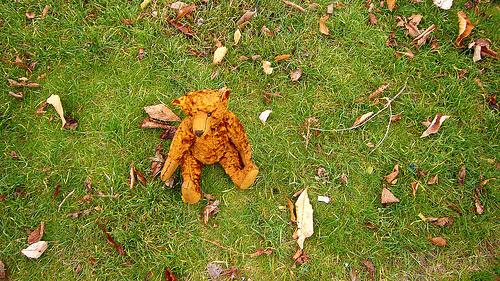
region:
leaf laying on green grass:
[45, 92, 77, 134]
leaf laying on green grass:
[26, 220, 42, 242]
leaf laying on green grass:
[18, 239, 47, 259]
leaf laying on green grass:
[293, 189, 314, 258]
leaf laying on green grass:
[128, 164, 133, 191]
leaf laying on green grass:
[133, 165, 147, 185]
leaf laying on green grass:
[164, 13, 196, 38]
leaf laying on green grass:
[418, 112, 451, 135]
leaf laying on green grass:
[378, 186, 399, 202]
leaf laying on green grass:
[383, 162, 400, 184]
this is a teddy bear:
[134, 84, 254, 205]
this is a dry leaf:
[289, 191, 327, 264]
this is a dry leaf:
[367, 168, 409, 218]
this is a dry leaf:
[251, 100, 291, 139]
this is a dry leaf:
[14, 213, 60, 263]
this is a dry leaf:
[40, 83, 84, 134]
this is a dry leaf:
[391, 9, 442, 64]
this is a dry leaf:
[164, 5, 198, 41]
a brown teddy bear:
[153, 77, 258, 207]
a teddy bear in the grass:
[116, 70, 295, 214]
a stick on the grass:
[326, 85, 406, 150]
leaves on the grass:
[160, 0, 290, 88]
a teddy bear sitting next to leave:
[130, 96, 247, 218]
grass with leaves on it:
[1, 2, 497, 276]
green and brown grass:
[0, 2, 477, 274]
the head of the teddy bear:
[170, 85, 237, 135]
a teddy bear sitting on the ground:
[152, 75, 263, 215]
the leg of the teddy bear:
[221, 153, 255, 184]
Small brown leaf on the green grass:
[282, 179, 336, 266]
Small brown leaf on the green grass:
[198, 180, 235, 234]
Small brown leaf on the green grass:
[80, 204, 171, 279]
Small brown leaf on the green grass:
[12, 219, 47, 255]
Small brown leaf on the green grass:
[33, 85, 74, 134]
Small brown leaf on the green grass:
[197, 28, 229, 74]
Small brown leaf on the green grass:
[210, 12, 259, 51]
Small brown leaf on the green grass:
[236, 6, 276, 33]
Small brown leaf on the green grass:
[253, 98, 278, 138]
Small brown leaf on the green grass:
[419, 101, 465, 178]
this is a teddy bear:
[105, 70, 290, 231]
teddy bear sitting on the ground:
[125, 71, 275, 218]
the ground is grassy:
[65, 40, 401, 273]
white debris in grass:
[313, 185, 338, 215]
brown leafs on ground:
[22, 36, 445, 272]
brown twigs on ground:
[302, 65, 447, 166]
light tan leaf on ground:
[267, 166, 328, 259]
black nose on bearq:
[181, 115, 211, 146]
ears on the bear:
[162, 90, 252, 120]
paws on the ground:
[148, 151, 277, 181]